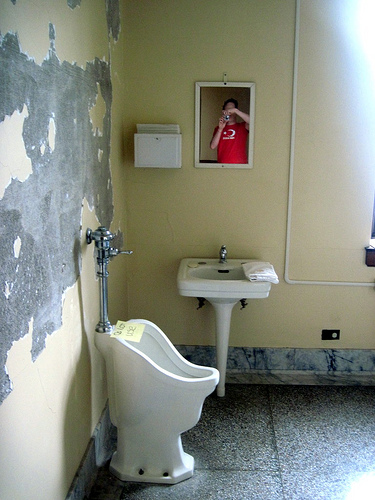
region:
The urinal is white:
[169, 361, 249, 453]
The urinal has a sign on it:
[97, 309, 162, 360]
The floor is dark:
[248, 397, 346, 488]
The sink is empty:
[181, 238, 277, 333]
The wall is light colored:
[22, 359, 97, 450]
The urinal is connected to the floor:
[76, 442, 228, 493]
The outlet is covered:
[309, 308, 360, 361]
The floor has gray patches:
[12, 148, 135, 363]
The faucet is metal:
[203, 243, 236, 260]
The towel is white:
[234, 253, 292, 305]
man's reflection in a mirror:
[208, 94, 251, 164]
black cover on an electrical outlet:
[317, 325, 342, 342]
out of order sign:
[110, 313, 148, 345]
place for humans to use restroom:
[89, 308, 226, 486]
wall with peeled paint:
[1, 17, 124, 221]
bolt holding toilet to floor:
[131, 460, 149, 483]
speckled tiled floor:
[245, 395, 342, 490]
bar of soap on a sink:
[182, 252, 202, 274]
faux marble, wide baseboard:
[256, 345, 370, 386]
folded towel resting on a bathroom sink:
[238, 255, 282, 286]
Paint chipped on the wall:
[9, 47, 67, 189]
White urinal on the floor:
[105, 325, 249, 485]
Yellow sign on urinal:
[114, 315, 152, 348]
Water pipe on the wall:
[270, 164, 327, 315]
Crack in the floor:
[226, 418, 266, 491]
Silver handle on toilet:
[77, 210, 132, 330]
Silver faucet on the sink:
[213, 235, 237, 273]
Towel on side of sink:
[242, 255, 283, 294]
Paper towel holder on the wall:
[127, 114, 202, 186]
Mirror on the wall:
[189, 73, 273, 176]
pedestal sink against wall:
[152, 231, 290, 409]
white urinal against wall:
[49, 211, 229, 491]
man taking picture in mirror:
[174, 59, 279, 188]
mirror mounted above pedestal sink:
[166, 57, 301, 324]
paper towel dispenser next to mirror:
[124, 107, 264, 218]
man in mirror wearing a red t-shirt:
[165, 87, 271, 175]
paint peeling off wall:
[9, 14, 130, 395]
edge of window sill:
[357, 179, 374, 278]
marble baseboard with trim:
[161, 317, 373, 405]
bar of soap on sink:
[167, 231, 285, 307]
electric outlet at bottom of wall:
[312, 323, 346, 343]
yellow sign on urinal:
[105, 310, 154, 346]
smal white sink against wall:
[172, 237, 278, 419]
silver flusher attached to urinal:
[110, 245, 135, 262]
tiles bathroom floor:
[227, 384, 365, 479]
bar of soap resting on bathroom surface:
[185, 257, 202, 273]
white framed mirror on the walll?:
[185, 66, 266, 173]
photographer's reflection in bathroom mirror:
[204, 93, 248, 163]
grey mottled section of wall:
[22, 21, 117, 154]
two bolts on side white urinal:
[129, 463, 175, 481]